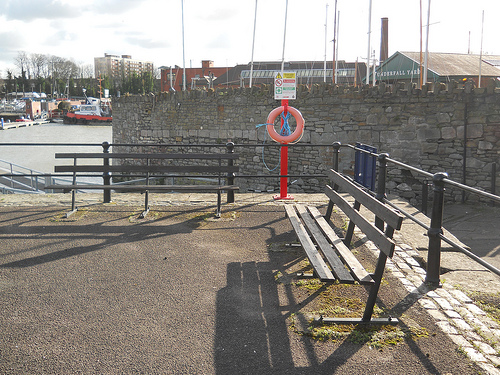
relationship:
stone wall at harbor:
[111, 80, 499, 208] [0, 80, 498, 373]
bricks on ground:
[321, 201, 493, 373] [0, 188, 498, 371]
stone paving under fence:
[3, 192, 498, 372] [1, 139, 498, 322]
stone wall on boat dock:
[108, 77, 496, 202] [2, 78, 110, 133]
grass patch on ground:
[306, 290, 409, 350] [16, 238, 464, 366]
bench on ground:
[52, 152, 240, 218] [0, 188, 498, 371]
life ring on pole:
[266, 105, 306, 143] [281, 99, 288, 199]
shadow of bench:
[209, 256, 326, 373] [282, 167, 404, 323]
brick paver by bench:
[418, 295, 435, 310] [282, 167, 404, 323]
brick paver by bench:
[451, 317, 468, 330] [282, 167, 404, 323]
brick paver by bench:
[466, 298, 485, 315] [282, 167, 404, 323]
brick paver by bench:
[406, 271, 422, 283] [282, 167, 404, 323]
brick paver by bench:
[396, 260, 410, 270] [282, 167, 404, 323]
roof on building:
[377, 48, 495, 75] [371, 51, 498, 87]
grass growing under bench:
[299, 294, 409, 345] [263, 156, 401, 333]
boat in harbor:
[59, 105, 109, 126] [0, 89, 111, 185]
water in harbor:
[19, 122, 111, 184] [0, 73, 498, 207]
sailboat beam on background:
[365, 0, 375, 83] [119, 55, 497, 87]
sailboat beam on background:
[281, 0, 293, 72] [119, 55, 497, 87]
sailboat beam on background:
[248, 0, 263, 85] [119, 55, 497, 87]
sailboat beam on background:
[180, 0, 191, 96] [119, 55, 497, 87]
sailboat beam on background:
[420, 0, 433, 83] [119, 55, 497, 87]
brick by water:
[334, 111, 366, 131] [5, 122, 111, 182]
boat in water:
[59, 105, 109, 126] [5, 122, 111, 182]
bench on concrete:
[295, 160, 403, 304] [227, 203, 415, 343]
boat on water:
[64, 94, 109, 122] [51, 122, 89, 137]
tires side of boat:
[62, 116, 91, 123] [62, 99, 111, 128]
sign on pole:
[273, 71, 298, 99] [279, 100, 291, 195]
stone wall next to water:
[111, 80, 499, 208] [0, 119, 110, 190]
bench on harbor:
[282, 167, 404, 323] [0, 90, 83, 133]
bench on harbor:
[52, 152, 240, 218] [0, 90, 83, 133]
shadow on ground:
[214, 260, 334, 373] [0, 188, 498, 371]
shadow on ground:
[1, 190, 278, 270] [0, 188, 498, 371]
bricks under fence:
[419, 290, 497, 374] [0, 134, 497, 298]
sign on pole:
[266, 67, 300, 102] [276, 96, 289, 198]